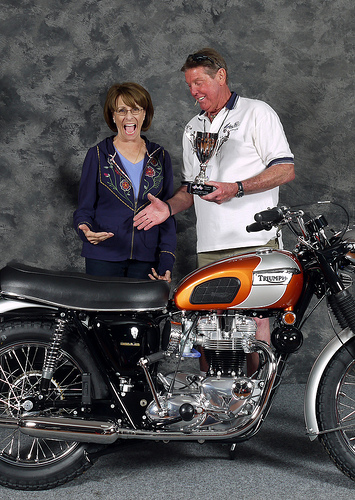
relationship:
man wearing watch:
[129, 48, 296, 380] [234, 177, 244, 199]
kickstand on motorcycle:
[228, 440, 237, 451] [2, 202, 354, 492]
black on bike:
[194, 275, 241, 307] [21, 196, 336, 452]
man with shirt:
[129, 48, 296, 380] [181, 91, 297, 253]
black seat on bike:
[0, 259, 171, 315] [0, 201, 353, 491]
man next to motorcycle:
[132, 48, 301, 381] [32, 235, 311, 349]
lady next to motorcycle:
[70, 80, 181, 284] [32, 235, 311, 349]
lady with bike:
[70, 80, 181, 284] [0, 196, 355, 495]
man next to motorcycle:
[129, 48, 296, 380] [2, 202, 354, 492]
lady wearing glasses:
[70, 80, 181, 284] [112, 106, 142, 116]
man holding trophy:
[129, 48, 296, 380] [181, 124, 228, 199]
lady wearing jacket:
[70, 80, 181, 284] [80, 135, 193, 277]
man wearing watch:
[129, 48, 296, 380] [234, 173, 246, 199]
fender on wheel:
[302, 336, 344, 418] [300, 339, 354, 451]